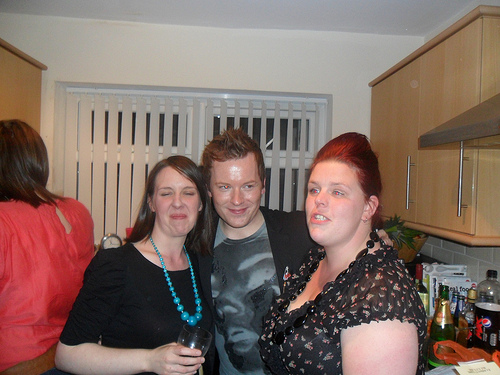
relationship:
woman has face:
[101, 151, 218, 374] [151, 174, 198, 246]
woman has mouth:
[101, 151, 218, 374] [166, 211, 191, 224]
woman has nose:
[101, 151, 218, 374] [169, 194, 184, 211]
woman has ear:
[101, 151, 218, 374] [147, 193, 158, 214]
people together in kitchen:
[15, 120, 458, 359] [29, 10, 500, 255]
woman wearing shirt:
[4, 131, 96, 332] [4, 216, 81, 358]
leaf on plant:
[393, 219, 410, 248] [388, 217, 414, 258]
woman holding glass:
[101, 151, 218, 374] [174, 326, 216, 367]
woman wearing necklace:
[101, 151, 218, 374] [160, 254, 206, 330]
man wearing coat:
[202, 147, 310, 365] [258, 212, 310, 283]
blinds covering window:
[81, 116, 315, 186] [55, 100, 321, 245]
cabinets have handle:
[368, 64, 489, 229] [399, 151, 429, 225]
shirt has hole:
[4, 216, 81, 358] [52, 201, 69, 228]